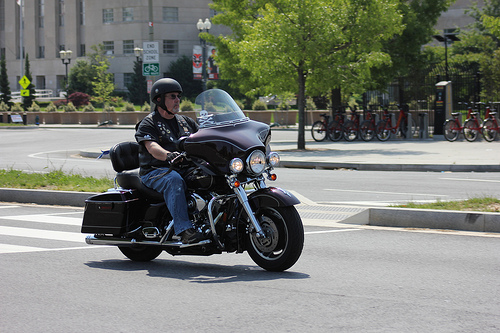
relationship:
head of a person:
[145, 77, 183, 115] [131, 77, 206, 247]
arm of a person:
[131, 122, 172, 162] [137, 77, 217, 246]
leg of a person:
[137, 170, 205, 242] [131, 77, 206, 247]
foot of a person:
[183, 228, 205, 243] [131, 77, 206, 247]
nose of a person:
[174, 97, 181, 107] [131, 77, 206, 247]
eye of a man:
[168, 94, 177, 101] [134, 77, 214, 249]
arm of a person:
[133, 122, 173, 162] [132, 77, 220, 253]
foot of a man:
[183, 228, 205, 241] [134, 77, 214, 249]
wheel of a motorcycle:
[238, 191, 305, 274] [78, 87, 306, 272]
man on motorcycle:
[134, 77, 214, 249] [78, 87, 306, 274]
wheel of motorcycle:
[238, 191, 305, 274] [78, 87, 306, 274]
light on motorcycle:
[245, 148, 265, 174] [78, 87, 306, 272]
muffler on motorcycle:
[83, 234, 139, 246] [78, 87, 306, 272]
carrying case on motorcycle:
[80, 190, 144, 234] [78, 87, 306, 272]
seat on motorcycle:
[107, 140, 157, 199] [78, 87, 306, 272]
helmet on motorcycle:
[149, 76, 182, 117] [78, 87, 306, 272]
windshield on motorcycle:
[192, 88, 249, 128] [78, 87, 306, 272]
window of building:
[97, 7, 115, 23] [4, 3, 237, 100]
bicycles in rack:
[309, 102, 497, 142] [313, 103, 499, 140]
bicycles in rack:
[440, 106, 499, 142] [440, 106, 499, 142]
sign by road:
[18, 74, 30, 99] [1, 126, 495, 328]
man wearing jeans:
[134, 77, 214, 249] [140, 165, 195, 233]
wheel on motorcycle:
[238, 191, 305, 274] [78, 87, 306, 274]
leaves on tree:
[216, 3, 406, 97] [206, 3, 409, 151]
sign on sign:
[18, 74, 30, 99] [18, 74, 30, 99]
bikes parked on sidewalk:
[321, 108, 483, 142] [322, 138, 479, 148]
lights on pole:
[199, 17, 222, 41] [189, 40, 212, 84]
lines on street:
[14, 216, 45, 253] [35, 267, 137, 314]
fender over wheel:
[257, 178, 285, 199] [238, 191, 305, 274]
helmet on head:
[149, 76, 182, 98] [145, 77, 176, 113]